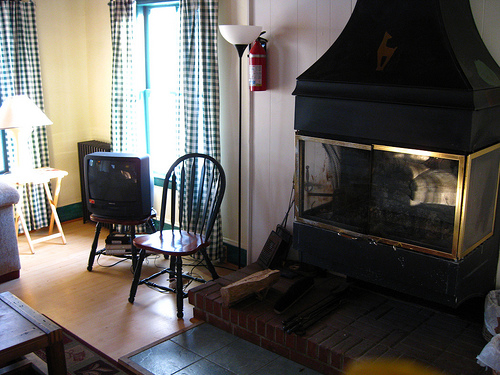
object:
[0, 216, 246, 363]
floor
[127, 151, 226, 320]
chair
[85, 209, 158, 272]
stand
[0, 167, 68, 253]
end table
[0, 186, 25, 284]
chair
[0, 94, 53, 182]
lamp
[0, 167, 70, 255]
folding table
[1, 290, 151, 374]
table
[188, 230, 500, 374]
hearth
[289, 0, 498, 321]
fire place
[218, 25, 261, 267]
lamp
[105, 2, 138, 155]
curtain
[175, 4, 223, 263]
curtain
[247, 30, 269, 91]
extinguisher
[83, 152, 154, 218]
television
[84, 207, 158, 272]
stool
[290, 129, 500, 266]
enclosure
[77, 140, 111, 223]
heater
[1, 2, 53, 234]
curtain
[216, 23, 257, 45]
shade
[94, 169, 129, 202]
small